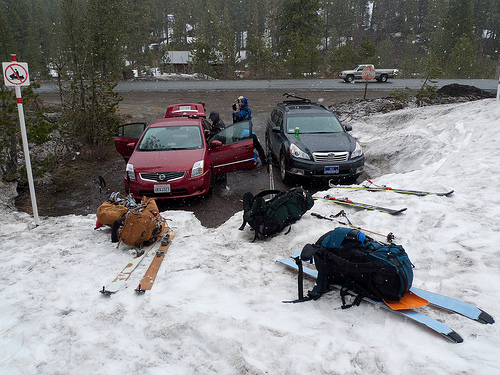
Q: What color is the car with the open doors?
A: Red.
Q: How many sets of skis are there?
A: Three.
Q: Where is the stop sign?
A: By the road.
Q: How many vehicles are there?
A: Three.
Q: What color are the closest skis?
A: Blue.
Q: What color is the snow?
A: White.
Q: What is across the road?
A: Trees.